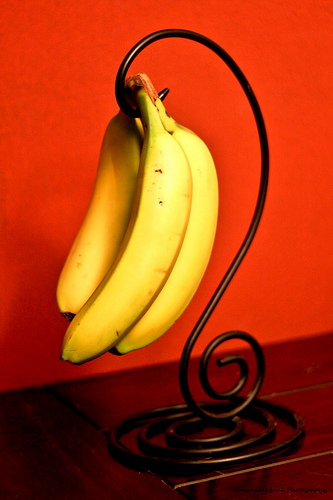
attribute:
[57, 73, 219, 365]
bananas — hanging, yellow, bunched, ripe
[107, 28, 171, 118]
hook — metal, curved, black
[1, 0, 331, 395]
wall — red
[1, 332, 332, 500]
table — brown, dark, dark brown, wooden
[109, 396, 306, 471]
base — circular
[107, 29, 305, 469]
banana stand — black, curvy, curved, curving